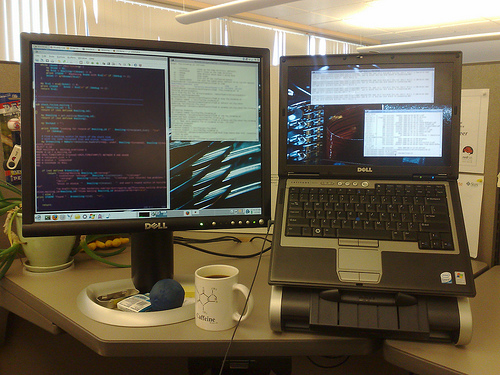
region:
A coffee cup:
[191, 259, 251, 329]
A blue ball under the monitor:
[147, 281, 187, 309]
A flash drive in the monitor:
[7, 133, 20, 173]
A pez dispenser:
[2, 95, 18, 181]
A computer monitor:
[16, 26, 266, 321]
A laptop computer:
[273, 51, 472, 298]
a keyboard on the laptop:
[286, 182, 451, 247]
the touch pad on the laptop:
[330, 243, 390, 280]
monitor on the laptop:
[286, 58, 456, 167]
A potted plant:
[1, 179, 140, 282]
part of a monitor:
[172, 127, 213, 180]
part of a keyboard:
[361, 212, 416, 257]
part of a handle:
[243, 294, 255, 320]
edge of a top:
[248, 337, 274, 357]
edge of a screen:
[161, 225, 193, 230]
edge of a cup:
[189, 270, 229, 293]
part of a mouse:
[339, 246, 374, 285]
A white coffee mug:
[191, 260, 254, 328]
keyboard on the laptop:
[290, 184, 450, 247]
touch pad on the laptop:
[334, 243, 391, 281]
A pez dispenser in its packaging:
[0, 87, 27, 192]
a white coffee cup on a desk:
[178, 260, 254, 352]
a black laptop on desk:
[257, 44, 483, 299]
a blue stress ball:
[143, 266, 195, 324]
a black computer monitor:
[17, 39, 285, 239]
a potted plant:
[11, 190, 88, 278]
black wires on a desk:
[158, 234, 272, 260]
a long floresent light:
[346, 25, 494, 57]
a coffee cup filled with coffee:
[172, 252, 252, 347]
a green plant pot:
[1, 205, 90, 285]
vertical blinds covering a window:
[15, 3, 177, 49]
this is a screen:
[29, 40, 277, 204]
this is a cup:
[195, 271, 225, 333]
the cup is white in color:
[212, 278, 230, 317]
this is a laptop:
[276, 55, 469, 310]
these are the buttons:
[318, 191, 438, 249]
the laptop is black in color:
[285, 248, 328, 290]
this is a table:
[31, 273, 100, 324]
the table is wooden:
[23, 274, 61, 305]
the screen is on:
[308, 76, 410, 128]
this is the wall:
[471, 59, 498, 161]